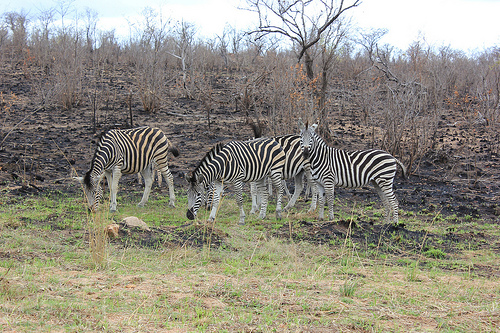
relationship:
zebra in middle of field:
[186, 137, 286, 226] [1, 176, 500, 332]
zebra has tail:
[296, 120, 407, 225] [396, 157, 408, 179]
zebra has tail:
[73, 126, 180, 213] [166, 135, 180, 158]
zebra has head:
[186, 137, 286, 226] [183, 170, 207, 220]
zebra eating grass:
[73, 126, 180, 213] [1, 190, 499, 332]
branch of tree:
[247, 30, 303, 45] [237, 1, 363, 80]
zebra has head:
[73, 126, 180, 213] [74, 173, 106, 213]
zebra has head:
[296, 120, 407, 225] [293, 118, 321, 159]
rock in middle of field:
[121, 216, 152, 232] [1, 176, 500, 332]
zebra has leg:
[73, 126, 180, 213] [151, 153, 175, 206]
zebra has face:
[296, 120, 407, 225] [299, 132, 314, 156]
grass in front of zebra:
[1, 190, 499, 332] [248, 135, 317, 214]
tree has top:
[237, 1, 363, 80] [237, 0, 363, 47]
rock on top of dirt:
[121, 216, 152, 232] [108, 220, 237, 246]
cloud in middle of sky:
[0, 16, 156, 45] [0, 1, 499, 62]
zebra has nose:
[186, 137, 286, 226] [186, 209, 196, 220]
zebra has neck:
[73, 126, 180, 213] [83, 133, 111, 177]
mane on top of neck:
[83, 128, 111, 188] [83, 133, 111, 177]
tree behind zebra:
[237, 1, 363, 80] [248, 135, 317, 214]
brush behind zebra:
[368, 121, 423, 177] [296, 120, 407, 225]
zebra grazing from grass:
[186, 137, 286, 226] [1, 190, 499, 332]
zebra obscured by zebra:
[248, 135, 317, 214] [186, 137, 286, 226]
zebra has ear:
[296, 120, 407, 225] [308, 119, 320, 131]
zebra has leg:
[296, 120, 407, 225] [312, 175, 335, 222]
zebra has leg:
[296, 120, 407, 225] [374, 175, 400, 224]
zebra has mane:
[186, 137, 286, 226] [190, 141, 226, 189]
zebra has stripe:
[296, 120, 407, 225] [357, 151, 389, 186]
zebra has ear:
[296, 120, 407, 225] [296, 119, 307, 132]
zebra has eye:
[296, 120, 407, 225] [310, 135, 315, 140]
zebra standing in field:
[186, 137, 286, 226] [1, 176, 500, 332]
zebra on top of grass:
[73, 126, 180, 213] [1, 190, 499, 332]